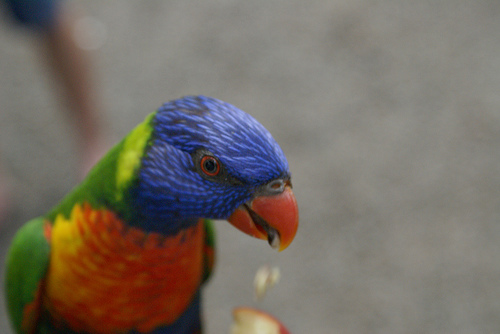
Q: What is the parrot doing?
A: Eating a seed.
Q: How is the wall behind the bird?
A: Grey.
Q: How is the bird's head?
A: Blue.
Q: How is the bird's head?
A: Blue.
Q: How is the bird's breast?
A: Yellow orange and red.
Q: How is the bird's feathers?
A: Yellow and orange.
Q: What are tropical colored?
A: Bird feathers.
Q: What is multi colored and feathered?
A: Bird.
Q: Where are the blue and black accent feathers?
A: Birds head.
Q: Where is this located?
A: Head of the bird.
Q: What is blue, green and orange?
A: Bird.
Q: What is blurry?
A: Background of the photo.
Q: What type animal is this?
A: A bird.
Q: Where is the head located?
A: Top of the bird.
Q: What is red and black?
A: The birds eyes.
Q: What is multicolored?
A: The bird.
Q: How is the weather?
A: Clear.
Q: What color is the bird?
A: Blue, orange, green and yellow.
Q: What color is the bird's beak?
A: Orange.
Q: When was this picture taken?
A: Daytime.